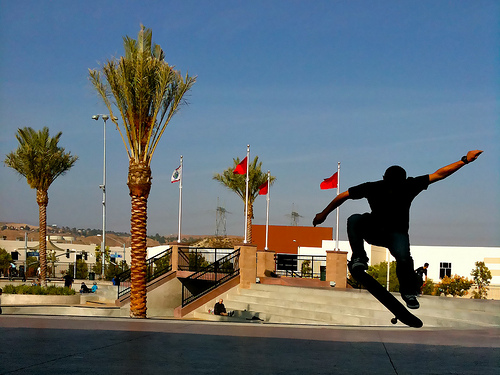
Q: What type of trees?
A: Palm.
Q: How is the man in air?
A: Skateboard.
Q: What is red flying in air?
A: Flags.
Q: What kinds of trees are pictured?
A: Palm trees.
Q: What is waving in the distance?
A: Different flags.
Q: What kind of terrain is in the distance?
A: Hills.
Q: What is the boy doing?
A: Skateboarding.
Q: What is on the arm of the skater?
A: A watch.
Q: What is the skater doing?
A: A trick.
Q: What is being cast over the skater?
A: A shadow.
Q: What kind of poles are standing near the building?
A: Flag poles.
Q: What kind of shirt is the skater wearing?
A: A T-shirt.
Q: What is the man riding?
A: Skateboard.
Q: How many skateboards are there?
A: 1.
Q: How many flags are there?
A: 4.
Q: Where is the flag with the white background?
A: The left side.